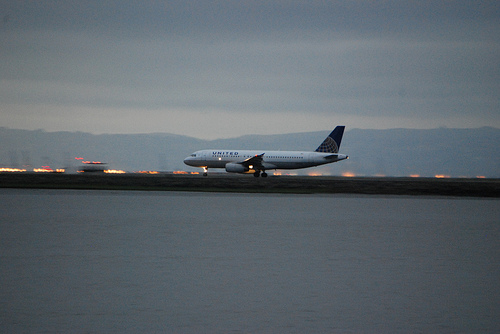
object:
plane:
[183, 125, 351, 178]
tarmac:
[278, 175, 375, 184]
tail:
[314, 125, 345, 158]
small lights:
[244, 157, 252, 162]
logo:
[211, 152, 239, 158]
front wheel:
[203, 167, 209, 176]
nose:
[183, 155, 190, 164]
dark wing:
[238, 153, 268, 178]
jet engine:
[225, 162, 248, 172]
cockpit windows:
[190, 154, 197, 158]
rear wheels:
[254, 170, 267, 177]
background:
[131, 150, 175, 168]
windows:
[266, 156, 303, 159]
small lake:
[0, 188, 500, 334]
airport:
[0, 157, 500, 180]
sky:
[0, 0, 500, 141]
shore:
[181, 185, 272, 197]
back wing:
[323, 154, 338, 159]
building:
[81, 162, 105, 171]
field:
[113, 174, 156, 181]